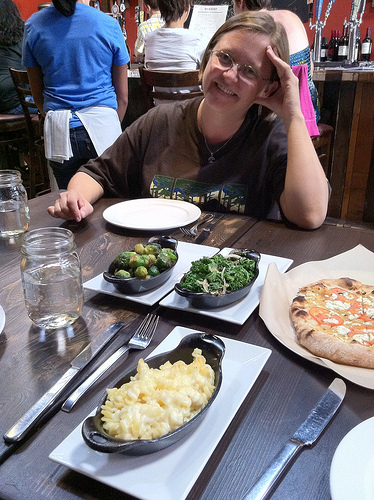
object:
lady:
[48, 12, 331, 229]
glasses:
[211, 51, 278, 79]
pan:
[81, 332, 226, 457]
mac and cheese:
[101, 349, 214, 440]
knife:
[243, 377, 346, 499]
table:
[0, 190, 374, 500]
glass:
[21, 227, 84, 331]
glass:
[0, 169, 29, 237]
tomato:
[310, 288, 373, 347]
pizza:
[291, 276, 373, 368]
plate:
[103, 195, 200, 233]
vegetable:
[178, 254, 257, 297]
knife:
[3, 318, 126, 443]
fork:
[63, 311, 158, 411]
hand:
[47, 189, 95, 222]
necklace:
[197, 107, 236, 165]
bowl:
[104, 234, 179, 294]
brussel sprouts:
[109, 243, 177, 279]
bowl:
[173, 247, 261, 308]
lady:
[138, 1, 207, 110]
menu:
[188, 5, 229, 32]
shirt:
[76, 95, 332, 227]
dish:
[101, 238, 179, 294]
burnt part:
[293, 295, 314, 340]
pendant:
[208, 156, 214, 164]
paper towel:
[259, 243, 373, 394]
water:
[24, 265, 84, 326]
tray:
[159, 245, 295, 326]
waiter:
[23, 1, 130, 187]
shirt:
[21, 4, 131, 128]